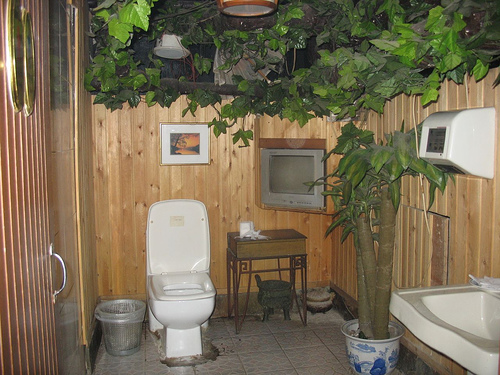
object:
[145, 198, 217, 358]
toilet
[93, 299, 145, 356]
bucket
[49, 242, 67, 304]
door handle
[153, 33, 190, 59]
lamp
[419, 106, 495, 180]
air hand dryer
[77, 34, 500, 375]
bathroom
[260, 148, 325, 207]
tv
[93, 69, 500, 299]
wall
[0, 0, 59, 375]
door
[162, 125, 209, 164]
picture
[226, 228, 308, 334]
small table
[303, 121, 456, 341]
potted plant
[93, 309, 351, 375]
floor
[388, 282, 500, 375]
sink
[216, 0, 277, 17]
light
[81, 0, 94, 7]
ceiling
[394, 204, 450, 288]
access door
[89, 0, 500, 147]
green ivy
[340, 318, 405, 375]
flower pot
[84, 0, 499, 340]
tree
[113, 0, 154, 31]
green leaves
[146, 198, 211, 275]
toilet lid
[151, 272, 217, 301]
toilet seat